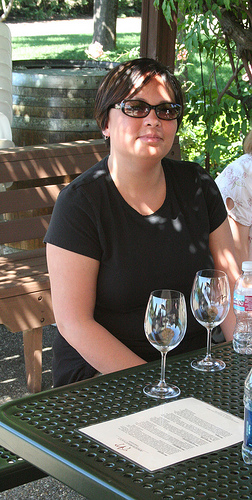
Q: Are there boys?
A: No, there are no boys.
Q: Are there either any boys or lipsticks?
A: No, there are no boys or lipsticks.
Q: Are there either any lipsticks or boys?
A: No, there are no boys or lipsticks.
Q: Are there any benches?
A: Yes, there is a bench.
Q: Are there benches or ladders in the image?
A: Yes, there is a bench.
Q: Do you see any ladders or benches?
A: Yes, there is a bench.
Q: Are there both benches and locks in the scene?
A: No, there is a bench but no locks.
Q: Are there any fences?
A: No, there are no fences.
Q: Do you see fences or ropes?
A: No, there are no fences or ropes.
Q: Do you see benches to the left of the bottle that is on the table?
A: Yes, there is a bench to the left of the bottle.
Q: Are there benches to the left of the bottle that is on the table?
A: Yes, there is a bench to the left of the bottle.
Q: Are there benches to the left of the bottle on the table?
A: Yes, there is a bench to the left of the bottle.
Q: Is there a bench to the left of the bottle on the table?
A: Yes, there is a bench to the left of the bottle.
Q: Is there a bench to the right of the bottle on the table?
A: No, the bench is to the left of the bottle.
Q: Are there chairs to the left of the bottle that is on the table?
A: No, there is a bench to the left of the bottle.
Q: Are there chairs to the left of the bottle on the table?
A: No, there is a bench to the left of the bottle.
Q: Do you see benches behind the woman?
A: Yes, there is a bench behind the woman.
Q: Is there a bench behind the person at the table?
A: Yes, there is a bench behind the woman.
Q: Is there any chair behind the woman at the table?
A: No, there is a bench behind the woman.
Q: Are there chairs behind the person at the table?
A: No, there is a bench behind the woman.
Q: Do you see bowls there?
A: No, there are no bowls.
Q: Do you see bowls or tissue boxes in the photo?
A: No, there are no bowls or tissue boxes.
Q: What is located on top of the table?
A: The menu is on top of the table.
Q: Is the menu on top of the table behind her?
A: Yes, the menu is on top of the table.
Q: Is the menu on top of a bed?
A: No, the menu is on top of the table.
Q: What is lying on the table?
A: The menu is lying on the table.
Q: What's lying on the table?
A: The menu is lying on the table.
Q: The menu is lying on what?
A: The menu is lying on the table.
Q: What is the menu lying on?
A: The menu is lying on the table.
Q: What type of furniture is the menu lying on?
A: The menu is lying on the table.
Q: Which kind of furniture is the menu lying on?
A: The menu is lying on the table.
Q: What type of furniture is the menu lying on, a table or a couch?
A: The menu is lying on a table.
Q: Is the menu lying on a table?
A: Yes, the menu is lying on a table.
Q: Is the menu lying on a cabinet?
A: No, the menu is lying on a table.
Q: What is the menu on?
A: The menu is on the table.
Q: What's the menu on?
A: The menu is on the table.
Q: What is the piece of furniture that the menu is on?
A: The piece of furniture is a table.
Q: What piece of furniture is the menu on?
A: The menu is on the table.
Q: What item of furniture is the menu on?
A: The menu is on the table.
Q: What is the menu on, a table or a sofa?
A: The menu is on a table.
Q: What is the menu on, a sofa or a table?
A: The menu is on a table.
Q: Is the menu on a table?
A: Yes, the menu is on a table.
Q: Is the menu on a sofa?
A: No, the menu is on a table.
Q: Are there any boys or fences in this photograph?
A: No, there are no fences or boys.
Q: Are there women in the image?
A: Yes, there is a woman.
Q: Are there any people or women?
A: Yes, there is a woman.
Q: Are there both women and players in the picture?
A: No, there is a woman but no players.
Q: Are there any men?
A: No, there are no men.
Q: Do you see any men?
A: No, there are no men.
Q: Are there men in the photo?
A: No, there are no men.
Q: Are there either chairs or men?
A: No, there are no men or chairs.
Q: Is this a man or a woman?
A: This is a woman.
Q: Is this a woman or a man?
A: This is a woman.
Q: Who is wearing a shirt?
A: The woman is wearing a shirt.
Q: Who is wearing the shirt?
A: The woman is wearing a shirt.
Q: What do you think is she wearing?
A: The woman is wearing a shirt.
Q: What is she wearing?
A: The woman is wearing a shirt.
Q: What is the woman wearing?
A: The woman is wearing a shirt.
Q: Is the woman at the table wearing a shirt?
A: Yes, the woman is wearing a shirt.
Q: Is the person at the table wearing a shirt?
A: Yes, the woman is wearing a shirt.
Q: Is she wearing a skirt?
A: No, the woman is wearing a shirt.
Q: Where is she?
A: The woman is at the table.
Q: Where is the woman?
A: The woman is at the table.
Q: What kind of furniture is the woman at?
A: The woman is at the table.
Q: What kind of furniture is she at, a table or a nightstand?
A: The woman is at a table.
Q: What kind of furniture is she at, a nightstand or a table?
A: The woman is at a table.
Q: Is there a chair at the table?
A: No, there is a woman at the table.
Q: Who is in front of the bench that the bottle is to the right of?
A: The woman is in front of the bench.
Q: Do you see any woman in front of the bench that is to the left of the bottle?
A: Yes, there is a woman in front of the bench.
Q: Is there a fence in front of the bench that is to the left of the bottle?
A: No, there is a woman in front of the bench.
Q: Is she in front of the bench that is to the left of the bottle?
A: Yes, the woman is in front of the bench.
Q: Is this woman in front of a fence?
A: No, the woman is in front of the bench.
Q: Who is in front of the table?
A: The woman is in front of the table.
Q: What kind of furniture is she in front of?
A: The woman is in front of the table.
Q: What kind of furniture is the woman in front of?
A: The woman is in front of the table.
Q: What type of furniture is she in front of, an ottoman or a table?
A: The woman is in front of a table.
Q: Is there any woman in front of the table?
A: Yes, there is a woman in front of the table.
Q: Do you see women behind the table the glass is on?
A: No, the woman is in front of the table.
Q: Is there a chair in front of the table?
A: No, there is a woman in front of the table.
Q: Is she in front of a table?
A: Yes, the woman is in front of a table.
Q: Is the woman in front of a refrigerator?
A: No, the woman is in front of a table.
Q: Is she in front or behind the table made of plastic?
A: The woman is in front of the table.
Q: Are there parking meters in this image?
A: No, there are no parking meters.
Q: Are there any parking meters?
A: No, there are no parking meters.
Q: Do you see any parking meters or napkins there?
A: No, there are no parking meters or napkins.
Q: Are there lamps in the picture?
A: No, there are no lamps.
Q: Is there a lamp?
A: No, there are no lamps.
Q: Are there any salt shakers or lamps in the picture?
A: No, there are no lamps or salt shakers.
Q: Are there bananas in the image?
A: Yes, there are bananas.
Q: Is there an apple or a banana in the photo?
A: Yes, there are bananas.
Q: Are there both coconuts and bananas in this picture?
A: No, there are bananas but no coconuts.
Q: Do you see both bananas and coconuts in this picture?
A: No, there are bananas but no coconuts.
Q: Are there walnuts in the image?
A: No, there are no walnuts.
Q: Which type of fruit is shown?
A: The fruit is bananas.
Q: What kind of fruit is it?
A: The fruits are bananas.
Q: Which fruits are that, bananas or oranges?
A: These are bananas.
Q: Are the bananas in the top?
A: Yes, the bananas are in the top of the image.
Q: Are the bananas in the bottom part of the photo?
A: No, the bananas are in the top of the image.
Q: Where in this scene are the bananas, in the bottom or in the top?
A: The bananas are in the top of the image.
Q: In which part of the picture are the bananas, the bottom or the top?
A: The bananas are in the top of the image.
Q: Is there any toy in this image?
A: No, there are no toys.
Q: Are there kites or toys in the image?
A: No, there are no toys or kites.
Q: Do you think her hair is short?
A: Yes, the hair is short.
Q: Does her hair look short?
A: Yes, the hair is short.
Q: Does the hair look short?
A: Yes, the hair is short.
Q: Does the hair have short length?
A: Yes, the hair is short.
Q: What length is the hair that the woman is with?
A: The hair is short.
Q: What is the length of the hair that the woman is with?
A: The hair is short.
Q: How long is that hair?
A: The hair is short.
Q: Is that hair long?
A: No, the hair is short.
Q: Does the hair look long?
A: No, the hair is short.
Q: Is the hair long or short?
A: The hair is short.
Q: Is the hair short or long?
A: The hair is short.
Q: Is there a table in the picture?
A: Yes, there is a table.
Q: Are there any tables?
A: Yes, there is a table.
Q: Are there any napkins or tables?
A: Yes, there is a table.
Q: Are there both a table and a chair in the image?
A: No, there is a table but no chairs.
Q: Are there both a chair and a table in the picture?
A: No, there is a table but no chairs.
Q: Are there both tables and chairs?
A: No, there is a table but no chairs.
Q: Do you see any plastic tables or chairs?
A: Yes, there is a plastic table.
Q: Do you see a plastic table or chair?
A: Yes, there is a plastic table.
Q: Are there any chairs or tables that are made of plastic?
A: Yes, the table is made of plastic.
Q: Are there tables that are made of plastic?
A: Yes, there is a table that is made of plastic.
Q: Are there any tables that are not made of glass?
A: Yes, there is a table that is made of plastic.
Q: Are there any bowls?
A: No, there are no bowls.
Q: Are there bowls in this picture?
A: No, there are no bowls.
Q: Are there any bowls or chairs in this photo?
A: No, there are no bowls or chairs.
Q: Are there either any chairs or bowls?
A: No, there are no bowls or chairs.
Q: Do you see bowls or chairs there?
A: No, there are no bowls or chairs.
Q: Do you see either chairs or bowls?
A: No, there are no bowls or chairs.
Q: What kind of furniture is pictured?
A: The furniture is a table.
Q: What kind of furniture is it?
A: The piece of furniture is a table.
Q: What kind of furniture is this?
A: That is a table.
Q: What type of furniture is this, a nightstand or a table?
A: That is a table.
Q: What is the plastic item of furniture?
A: The piece of furniture is a table.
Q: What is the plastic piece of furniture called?
A: The piece of furniture is a table.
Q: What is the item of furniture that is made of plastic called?
A: The piece of furniture is a table.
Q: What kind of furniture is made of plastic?
A: The furniture is a table.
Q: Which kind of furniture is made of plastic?
A: The furniture is a table.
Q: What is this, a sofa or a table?
A: This is a table.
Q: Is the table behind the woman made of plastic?
A: Yes, the table is made of plastic.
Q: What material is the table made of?
A: The table is made of plastic.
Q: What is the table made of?
A: The table is made of plastic.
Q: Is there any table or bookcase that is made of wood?
A: No, there is a table but it is made of plastic.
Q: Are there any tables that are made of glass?
A: No, there is a table but it is made of plastic.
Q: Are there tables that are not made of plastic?
A: No, there is a table but it is made of plastic.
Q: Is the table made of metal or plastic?
A: The table is made of plastic.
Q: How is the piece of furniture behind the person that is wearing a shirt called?
A: The piece of furniture is a table.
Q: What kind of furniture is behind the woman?
A: The piece of furniture is a table.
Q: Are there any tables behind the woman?
A: Yes, there is a table behind the woman.